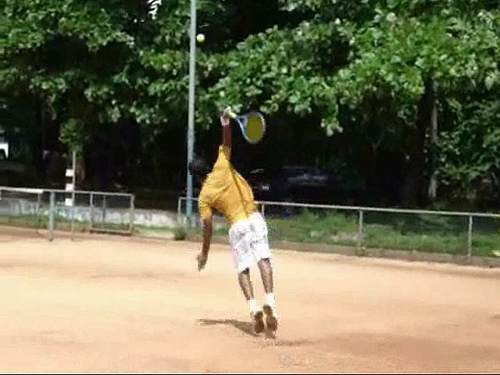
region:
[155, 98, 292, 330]
The man is playing tennis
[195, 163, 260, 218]
his shirt is yellow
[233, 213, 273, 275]
His shorts are white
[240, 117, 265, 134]
his racket is green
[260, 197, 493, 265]
The fence is made of metal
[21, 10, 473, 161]
the tree leaves are green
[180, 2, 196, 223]
the large pole is metal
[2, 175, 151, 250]
A metal fence keeps balls inside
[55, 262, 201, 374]
The ground is brown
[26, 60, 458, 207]
Many trees in the background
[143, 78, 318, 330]
man playing tennis on court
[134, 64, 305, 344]
man holding tennis racket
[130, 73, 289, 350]
man swinging tennis racket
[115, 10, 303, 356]
man serving tennis ball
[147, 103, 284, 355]
man winding up to hit ball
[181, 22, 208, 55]
tennis ball in the air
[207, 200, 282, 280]
white tennis shorts on man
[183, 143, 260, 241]
yellow tennis shirt on man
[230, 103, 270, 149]
blue and yellow racket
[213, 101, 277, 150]
hand holding tennis racket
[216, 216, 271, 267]
The player is wearin white shorts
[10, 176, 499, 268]
A fence by the tennis court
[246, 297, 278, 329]
The player is wearing white shoes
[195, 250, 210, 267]
The left hand of the player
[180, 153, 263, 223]
The player is wearing a yellow shirt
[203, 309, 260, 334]
A shadow on the ground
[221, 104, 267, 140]
A tennis racket in the player's right hand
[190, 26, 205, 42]
A yellow tennis ball in the air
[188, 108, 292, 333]
A man playing tennis on the court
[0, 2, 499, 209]
Trees behind the fence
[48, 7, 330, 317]
this is an action tennis scene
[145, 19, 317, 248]
he is reaching to hit the ball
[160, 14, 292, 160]
the ball is high above the player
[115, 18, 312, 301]
the player is trying to return a serve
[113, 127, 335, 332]
the tennis player is leaning forward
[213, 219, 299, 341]
he is wearing white shorts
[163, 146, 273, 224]
he has on a yellow shirt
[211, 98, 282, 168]
he is reaching back to hit the ball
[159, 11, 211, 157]
a pole in the background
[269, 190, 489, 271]
a gate in the area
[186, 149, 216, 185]
the head of a man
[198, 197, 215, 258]
the arm of a man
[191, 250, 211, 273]
the hand of a man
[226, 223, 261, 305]
the leg of a man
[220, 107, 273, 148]
a blue tennis racket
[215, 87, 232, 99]
a green tennis ball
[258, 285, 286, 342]
a white tennis shoe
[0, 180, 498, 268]
a gray metal railing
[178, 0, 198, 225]
a gray metal pole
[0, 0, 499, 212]
leafy green trees